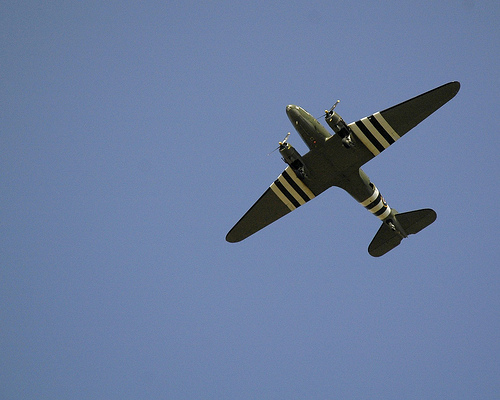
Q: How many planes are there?
A: One.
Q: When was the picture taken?
A: Daytime.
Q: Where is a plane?
A: In the air.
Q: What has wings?
A: The plane.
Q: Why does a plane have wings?
A: To fly.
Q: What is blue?
A: Sky.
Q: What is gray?
A: The airplane.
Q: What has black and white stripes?
A: Plane.